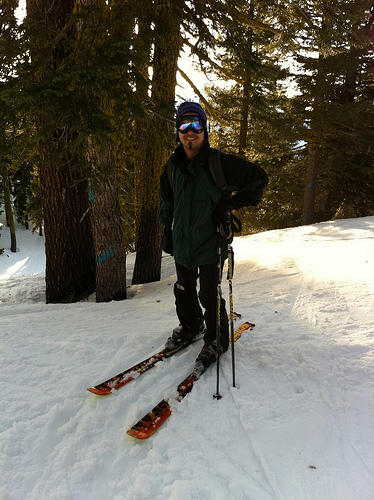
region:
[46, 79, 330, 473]
The person is doing some skiing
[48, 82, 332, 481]
The man is in the mountains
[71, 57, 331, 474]
The man has skis on his feet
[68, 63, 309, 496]
The man is enjoying the outdoors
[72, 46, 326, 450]
The man is wearing a hat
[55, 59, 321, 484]
The man is wearing goggles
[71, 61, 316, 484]
The man is wearing a thick jacket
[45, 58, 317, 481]
The man is standing close to the trees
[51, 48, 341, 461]
The man is planning some fun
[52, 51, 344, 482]
The man is smiling happily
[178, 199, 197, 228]
the coat is green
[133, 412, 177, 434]
the skis are orange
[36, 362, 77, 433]
the snow is clumpy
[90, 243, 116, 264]
the tree has a blue mark on it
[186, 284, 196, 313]
the pants are black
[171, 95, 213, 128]
the hat is blue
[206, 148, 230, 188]
the strap is gray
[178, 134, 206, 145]
the man is smiling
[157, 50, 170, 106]
the tree has moss on it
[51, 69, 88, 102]
the tree has green pine needles on it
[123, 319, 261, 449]
Two red skis on the man's feet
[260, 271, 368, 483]
Thick white snow covers the ground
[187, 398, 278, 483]
Ski tracks throughout the snow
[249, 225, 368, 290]
The sun shining brightly on the snow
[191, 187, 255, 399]
Black ski poles in the man's hand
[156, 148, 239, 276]
A green jacket on the man in the snow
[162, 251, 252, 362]
Black pants on the man's legs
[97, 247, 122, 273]
Blue spray paint on the tree trunk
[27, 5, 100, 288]
A large tree behind the skier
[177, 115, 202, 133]
Reflective goggles on the man's face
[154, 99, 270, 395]
Man posing and smiling for a picture.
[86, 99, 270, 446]
Man standing on his skis.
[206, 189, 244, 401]
Man holding the ski sticks.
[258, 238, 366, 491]
Ground covered of snow.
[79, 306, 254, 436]
Skis are red, black and yellow.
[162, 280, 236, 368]
Man wearing snow boots.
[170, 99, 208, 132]
Man wearing sunglasses and hat.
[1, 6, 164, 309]
Tall trees in the background.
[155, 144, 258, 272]
Man wearing green snow jacket.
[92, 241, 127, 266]
Blue paint on the tall tree.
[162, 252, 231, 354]
Man is wearing pants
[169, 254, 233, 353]
Man is wearing black pants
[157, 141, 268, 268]
Man is wearing a jacket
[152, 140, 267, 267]
Man is wearing a green and black jacket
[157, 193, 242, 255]
Man is wearing gloves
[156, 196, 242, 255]
Man is wearing black gloves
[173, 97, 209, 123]
Man is wearing a hat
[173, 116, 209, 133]
Man is wearing goggles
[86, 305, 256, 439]
Man is wearing skis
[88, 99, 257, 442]
Man is standing on snow